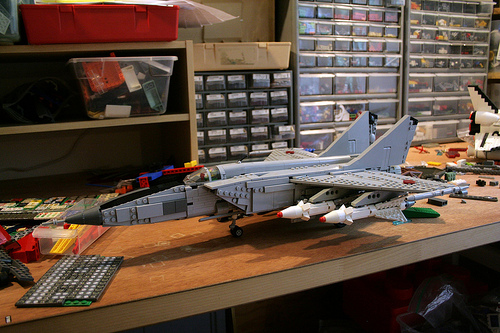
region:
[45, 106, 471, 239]
a Lego plane sitting on a table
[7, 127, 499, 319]
a long table holding assorted pieces of legos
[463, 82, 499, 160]
the end of another lego plane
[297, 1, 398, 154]
boxes full of lego peices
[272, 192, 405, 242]
lego missles on the plane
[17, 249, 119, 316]
a long flat Lego sitting on the table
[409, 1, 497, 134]
more boxes full of Lego pieces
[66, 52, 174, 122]
a big box sitting on the shelf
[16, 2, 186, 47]
a long red container on the shelf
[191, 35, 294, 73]
a beige container sitting on another box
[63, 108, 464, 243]
large lego fighter jet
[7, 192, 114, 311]
extra lego pieces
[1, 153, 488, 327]
long wood shop bench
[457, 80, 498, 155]
tail of lego space shuttle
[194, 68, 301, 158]
box with many drawers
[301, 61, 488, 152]
shelves with plastic boxes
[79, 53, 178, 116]
clear plastic box full of lego toys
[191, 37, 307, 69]
tan colored plastic box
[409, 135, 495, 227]
many grey lego pieces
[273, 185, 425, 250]
lego missiles under fighter jet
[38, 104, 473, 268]
large gray lego plane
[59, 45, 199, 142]
transparent box on shelf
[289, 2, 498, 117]
two chests of small drawers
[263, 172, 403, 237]
white lego missiles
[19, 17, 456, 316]
lego workshop bench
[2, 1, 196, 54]
red container on top shelf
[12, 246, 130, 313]
gray lego board on table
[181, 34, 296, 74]
manila colored plastic container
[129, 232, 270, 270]
wooden surface with shadow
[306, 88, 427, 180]
plastic tail wings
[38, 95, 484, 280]
the spaceship is made of lego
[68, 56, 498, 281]
the spaceship is gray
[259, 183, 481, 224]
the missiles are white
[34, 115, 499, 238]
the aircraft is on the table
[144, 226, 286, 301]
the table is brown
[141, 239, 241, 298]
the table is made of wood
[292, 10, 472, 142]
the shelf is organized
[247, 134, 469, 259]
the aircraft's wings are gray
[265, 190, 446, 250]
the aircraft has two missiles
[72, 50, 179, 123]
the container is in the shelf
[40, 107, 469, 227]
Jet made out of Lego's.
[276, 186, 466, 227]
Missiles made out of Lego's.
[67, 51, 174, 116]
Clear tub of Lego's.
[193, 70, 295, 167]
Little containers holding various items.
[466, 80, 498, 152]
White and black end of a Lego aircraft.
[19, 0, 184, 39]
Red container up on a shelf.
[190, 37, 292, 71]
Tan colored container.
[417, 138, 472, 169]
Various Lego's strewn around on desk.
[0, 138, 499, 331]
Wooden desk with Lego's on it.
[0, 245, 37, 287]
Dark colored Lego